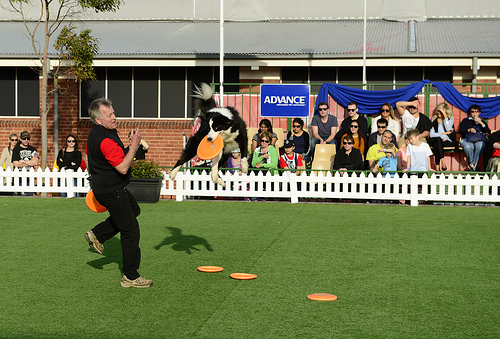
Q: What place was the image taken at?
A: It was taken at the field.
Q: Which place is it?
A: It is a field.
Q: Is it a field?
A: Yes, it is a field.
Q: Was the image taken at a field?
A: Yes, it was taken in a field.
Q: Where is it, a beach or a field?
A: It is a field.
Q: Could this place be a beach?
A: No, it is a field.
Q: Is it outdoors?
A: Yes, it is outdoors.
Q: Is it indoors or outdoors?
A: It is outdoors.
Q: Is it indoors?
A: No, it is outdoors.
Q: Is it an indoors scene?
A: No, it is outdoors.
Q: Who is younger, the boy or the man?
A: The boy is younger than the man.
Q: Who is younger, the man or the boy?
A: The boy is younger than the man.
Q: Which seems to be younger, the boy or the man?
A: The boy is younger than the man.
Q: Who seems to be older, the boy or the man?
A: The man is older than the boy.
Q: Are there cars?
A: No, there are no cars.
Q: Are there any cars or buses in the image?
A: No, there are no cars or buses.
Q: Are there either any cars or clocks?
A: No, there are no cars or clocks.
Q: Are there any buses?
A: No, there are no buses.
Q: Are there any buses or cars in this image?
A: No, there are no buses or cars.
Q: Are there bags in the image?
A: No, there are no bags.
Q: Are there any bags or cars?
A: No, there are no bags or cars.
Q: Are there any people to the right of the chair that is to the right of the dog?
A: Yes, there are people to the right of the chair.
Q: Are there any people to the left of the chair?
A: No, the people are to the right of the chair.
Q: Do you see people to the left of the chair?
A: No, the people are to the right of the chair.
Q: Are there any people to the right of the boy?
A: Yes, there are people to the right of the boy.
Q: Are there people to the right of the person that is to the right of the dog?
A: Yes, there are people to the right of the boy.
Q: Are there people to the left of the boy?
A: No, the people are to the right of the boy.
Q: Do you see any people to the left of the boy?
A: No, the people are to the right of the boy.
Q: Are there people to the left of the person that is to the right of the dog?
A: No, the people are to the right of the boy.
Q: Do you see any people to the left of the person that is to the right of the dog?
A: No, the people are to the right of the boy.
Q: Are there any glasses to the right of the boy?
A: No, there are people to the right of the boy.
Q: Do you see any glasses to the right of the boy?
A: No, there are people to the right of the boy.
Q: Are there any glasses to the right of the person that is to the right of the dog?
A: No, there are people to the right of the boy.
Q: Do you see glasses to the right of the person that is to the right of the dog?
A: No, there are people to the right of the boy.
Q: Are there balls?
A: No, there are no balls.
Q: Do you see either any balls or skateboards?
A: No, there are no balls or skateboards.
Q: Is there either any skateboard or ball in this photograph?
A: No, there are no balls or skateboards.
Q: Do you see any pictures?
A: No, there are no pictures.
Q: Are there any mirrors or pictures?
A: No, there are no pictures or mirrors.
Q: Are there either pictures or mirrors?
A: No, there are no pictures or mirrors.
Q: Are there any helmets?
A: No, there are no helmets.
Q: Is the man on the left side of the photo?
A: Yes, the man is on the left of the image.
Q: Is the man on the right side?
A: No, the man is on the left of the image.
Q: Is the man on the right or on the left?
A: The man is on the left of the image.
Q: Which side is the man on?
A: The man is on the left of the image.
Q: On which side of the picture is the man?
A: The man is on the left of the image.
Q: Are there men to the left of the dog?
A: Yes, there is a man to the left of the dog.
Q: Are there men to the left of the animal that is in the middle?
A: Yes, there is a man to the left of the dog.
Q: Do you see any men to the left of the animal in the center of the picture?
A: Yes, there is a man to the left of the dog.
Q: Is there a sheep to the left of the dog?
A: No, there is a man to the left of the dog.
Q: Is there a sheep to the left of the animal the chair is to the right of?
A: No, there is a man to the left of the dog.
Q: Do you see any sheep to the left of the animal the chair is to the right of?
A: No, there is a man to the left of the dog.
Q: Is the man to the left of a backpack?
A: No, the man is to the left of the dog.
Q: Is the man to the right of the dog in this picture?
A: No, the man is to the left of the dog.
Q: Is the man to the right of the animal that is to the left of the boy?
A: No, the man is to the left of the dog.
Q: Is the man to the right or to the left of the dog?
A: The man is to the left of the dog.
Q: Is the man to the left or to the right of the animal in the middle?
A: The man is to the left of the dog.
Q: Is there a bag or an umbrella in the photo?
A: No, there are no bags or umbrellas.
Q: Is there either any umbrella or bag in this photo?
A: No, there are no bags or umbrellas.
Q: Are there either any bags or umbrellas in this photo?
A: No, there are no bags or umbrellas.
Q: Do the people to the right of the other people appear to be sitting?
A: Yes, the people are sitting.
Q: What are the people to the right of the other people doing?
A: The people are sitting.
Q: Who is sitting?
A: The people are sitting.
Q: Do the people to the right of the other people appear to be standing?
A: No, the people are sitting.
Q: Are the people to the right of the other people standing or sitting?
A: The people are sitting.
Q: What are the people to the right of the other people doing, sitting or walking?
A: The people are sitting.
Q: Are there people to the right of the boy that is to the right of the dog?
A: Yes, there are people to the right of the boy.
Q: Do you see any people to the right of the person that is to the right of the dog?
A: Yes, there are people to the right of the boy.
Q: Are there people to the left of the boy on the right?
A: No, the people are to the right of the boy.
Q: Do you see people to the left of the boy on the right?
A: No, the people are to the right of the boy.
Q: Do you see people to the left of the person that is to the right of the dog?
A: No, the people are to the right of the boy.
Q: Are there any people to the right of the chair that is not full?
A: Yes, there are people to the right of the chair.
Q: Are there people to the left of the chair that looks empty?
A: No, the people are to the right of the chair.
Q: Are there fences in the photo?
A: Yes, there is a fence.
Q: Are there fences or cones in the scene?
A: Yes, there is a fence.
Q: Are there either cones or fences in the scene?
A: Yes, there is a fence.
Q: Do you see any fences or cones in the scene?
A: Yes, there is a fence.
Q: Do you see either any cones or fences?
A: Yes, there is a fence.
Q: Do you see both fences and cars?
A: No, there is a fence but no cars.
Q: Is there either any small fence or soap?
A: Yes, there is a small fence.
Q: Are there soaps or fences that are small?
A: Yes, the fence is small.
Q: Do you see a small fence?
A: Yes, there is a small fence.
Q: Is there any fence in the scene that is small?
A: Yes, there is a fence that is small.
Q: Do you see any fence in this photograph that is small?
A: Yes, there is a fence that is small.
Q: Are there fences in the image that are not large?
A: Yes, there is a small fence.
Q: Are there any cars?
A: No, there are no cars.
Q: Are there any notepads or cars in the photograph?
A: No, there are no cars or notepads.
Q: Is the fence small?
A: Yes, the fence is small.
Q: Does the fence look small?
A: Yes, the fence is small.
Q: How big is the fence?
A: The fence is small.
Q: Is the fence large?
A: No, the fence is small.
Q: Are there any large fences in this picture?
A: No, there is a fence but it is small.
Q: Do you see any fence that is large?
A: No, there is a fence but it is small.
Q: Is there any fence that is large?
A: No, there is a fence but it is small.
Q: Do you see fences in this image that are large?
A: No, there is a fence but it is small.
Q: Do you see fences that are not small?
A: No, there is a fence but it is small.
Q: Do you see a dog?
A: Yes, there is a dog.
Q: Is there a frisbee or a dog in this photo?
A: Yes, there is a dog.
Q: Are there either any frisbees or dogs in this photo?
A: Yes, there is a dog.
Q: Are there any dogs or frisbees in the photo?
A: Yes, there is a dog.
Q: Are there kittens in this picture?
A: No, there are no kittens.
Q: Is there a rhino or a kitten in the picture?
A: No, there are no kittens or rhinos.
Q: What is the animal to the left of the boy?
A: The animal is a dog.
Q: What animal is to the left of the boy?
A: The animal is a dog.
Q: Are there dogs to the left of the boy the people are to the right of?
A: Yes, there is a dog to the left of the boy.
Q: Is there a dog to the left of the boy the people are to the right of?
A: Yes, there is a dog to the left of the boy.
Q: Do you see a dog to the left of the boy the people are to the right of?
A: Yes, there is a dog to the left of the boy.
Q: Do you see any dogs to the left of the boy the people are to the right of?
A: Yes, there is a dog to the left of the boy.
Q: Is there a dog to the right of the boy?
A: No, the dog is to the left of the boy.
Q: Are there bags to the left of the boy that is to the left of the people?
A: No, there is a dog to the left of the boy.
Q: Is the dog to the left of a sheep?
A: No, the dog is to the left of the boy.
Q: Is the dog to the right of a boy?
A: No, the dog is to the left of a boy.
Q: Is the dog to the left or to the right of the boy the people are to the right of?
A: The dog is to the left of the boy.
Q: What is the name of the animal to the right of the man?
A: The animal is a dog.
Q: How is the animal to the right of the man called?
A: The animal is a dog.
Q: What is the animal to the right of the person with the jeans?
A: The animal is a dog.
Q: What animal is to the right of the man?
A: The animal is a dog.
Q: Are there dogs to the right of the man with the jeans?
A: Yes, there is a dog to the right of the man.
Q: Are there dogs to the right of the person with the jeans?
A: Yes, there is a dog to the right of the man.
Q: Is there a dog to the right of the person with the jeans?
A: Yes, there is a dog to the right of the man.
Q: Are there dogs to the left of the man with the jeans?
A: No, the dog is to the right of the man.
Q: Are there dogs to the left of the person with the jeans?
A: No, the dog is to the right of the man.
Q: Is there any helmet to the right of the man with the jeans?
A: No, there is a dog to the right of the man.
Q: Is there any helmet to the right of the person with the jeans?
A: No, there is a dog to the right of the man.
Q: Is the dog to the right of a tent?
A: No, the dog is to the right of a man.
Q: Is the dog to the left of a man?
A: No, the dog is to the right of a man.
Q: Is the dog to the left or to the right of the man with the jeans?
A: The dog is to the right of the man.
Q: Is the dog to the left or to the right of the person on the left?
A: The dog is to the right of the man.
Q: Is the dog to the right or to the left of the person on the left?
A: The dog is to the right of the man.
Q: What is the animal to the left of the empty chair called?
A: The animal is a dog.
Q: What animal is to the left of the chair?
A: The animal is a dog.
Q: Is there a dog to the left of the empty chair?
A: Yes, there is a dog to the left of the chair.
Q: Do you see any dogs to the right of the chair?
A: No, the dog is to the left of the chair.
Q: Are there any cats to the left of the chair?
A: No, there is a dog to the left of the chair.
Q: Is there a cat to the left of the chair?
A: No, there is a dog to the left of the chair.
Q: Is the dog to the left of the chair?
A: Yes, the dog is to the left of the chair.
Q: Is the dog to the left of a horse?
A: No, the dog is to the left of the chair.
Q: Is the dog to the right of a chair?
A: No, the dog is to the left of a chair.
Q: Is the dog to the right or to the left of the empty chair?
A: The dog is to the left of the chair.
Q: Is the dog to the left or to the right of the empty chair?
A: The dog is to the left of the chair.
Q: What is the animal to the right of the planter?
A: The animal is a dog.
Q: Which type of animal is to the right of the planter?
A: The animal is a dog.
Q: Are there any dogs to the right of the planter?
A: Yes, there is a dog to the right of the planter.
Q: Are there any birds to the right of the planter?
A: No, there is a dog to the right of the planter.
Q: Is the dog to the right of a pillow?
A: No, the dog is to the right of a planter.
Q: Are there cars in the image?
A: No, there are no cars.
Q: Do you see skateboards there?
A: No, there are no skateboards.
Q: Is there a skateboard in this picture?
A: No, there are no skateboards.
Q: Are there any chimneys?
A: No, there are no chimneys.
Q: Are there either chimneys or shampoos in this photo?
A: No, there are no chimneys or shampoos.